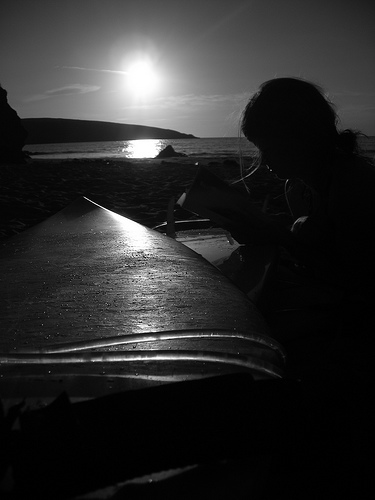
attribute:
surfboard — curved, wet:
[9, 194, 290, 498]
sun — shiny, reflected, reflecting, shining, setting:
[125, 64, 155, 98]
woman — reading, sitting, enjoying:
[234, 84, 375, 351]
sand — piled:
[154, 143, 192, 157]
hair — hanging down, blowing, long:
[244, 74, 357, 162]